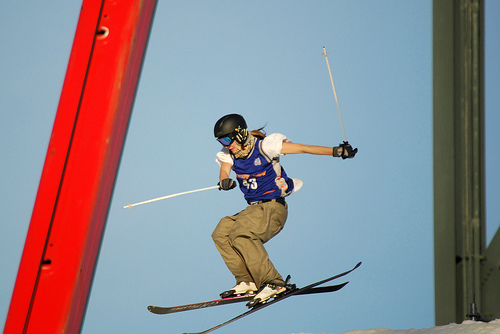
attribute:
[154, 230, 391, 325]
skis —  a pair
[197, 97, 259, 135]
helmet — black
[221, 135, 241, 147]
goggles — large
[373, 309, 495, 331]
snow — white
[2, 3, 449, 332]
sky — clear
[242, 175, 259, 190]
numbers — white